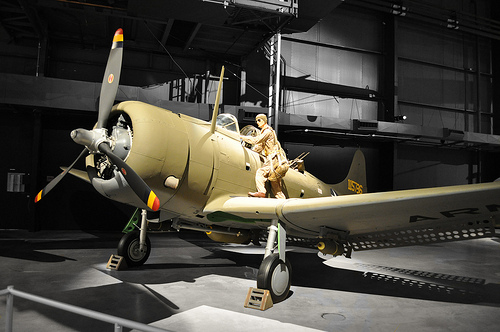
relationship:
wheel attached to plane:
[107, 220, 160, 267] [22, 38, 485, 300]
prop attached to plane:
[30, 22, 158, 223] [22, 38, 485, 300]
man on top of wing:
[241, 112, 292, 200] [208, 169, 498, 250]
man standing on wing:
[241, 112, 292, 200] [208, 169, 498, 250]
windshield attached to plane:
[213, 113, 236, 127] [22, 38, 485, 300]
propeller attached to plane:
[26, 21, 167, 224] [22, 38, 485, 300]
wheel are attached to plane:
[256, 253, 294, 303] [22, 38, 485, 300]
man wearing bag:
[241, 112, 292, 200] [262, 144, 292, 188]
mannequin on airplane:
[240, 112, 291, 199] [14, 21, 484, 322]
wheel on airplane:
[256, 248, 296, 303] [14, 21, 484, 322]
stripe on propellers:
[146, 190, 161, 211] [18, 21, 174, 221]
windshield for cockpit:
[216, 113, 233, 140] [237, 110, 261, 146]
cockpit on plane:
[237, 110, 261, 146] [16, 57, 483, 330]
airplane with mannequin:
[34, 27, 499, 303] [236, 108, 306, 197]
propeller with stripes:
[34, 27, 162, 213] [144, 186, 167, 218]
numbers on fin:
[345, 180, 368, 192] [345, 145, 371, 191]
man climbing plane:
[246, 111, 299, 194] [2, 21, 484, 277]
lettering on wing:
[405, 207, 484, 234] [216, 169, 484, 267]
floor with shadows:
[301, 296, 381, 329] [93, 253, 202, 330]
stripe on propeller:
[146, 190, 164, 207] [112, 148, 172, 228]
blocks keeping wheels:
[96, 250, 269, 312] [255, 254, 297, 298]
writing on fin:
[103, 70, 113, 81] [108, 144, 168, 210]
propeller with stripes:
[34, 27, 162, 213] [140, 188, 168, 214]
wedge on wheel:
[243, 279, 273, 312] [254, 256, 293, 293]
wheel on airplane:
[116, 230, 154, 269] [14, 21, 484, 322]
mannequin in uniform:
[240, 112, 291, 199] [242, 124, 287, 193]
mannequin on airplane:
[242, 106, 296, 196] [34, 27, 499, 303]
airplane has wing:
[14, 21, 484, 322] [213, 174, 498, 224]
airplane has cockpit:
[34, 27, 499, 303] [208, 108, 249, 135]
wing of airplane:
[224, 169, 483, 242] [34, 27, 499, 303]